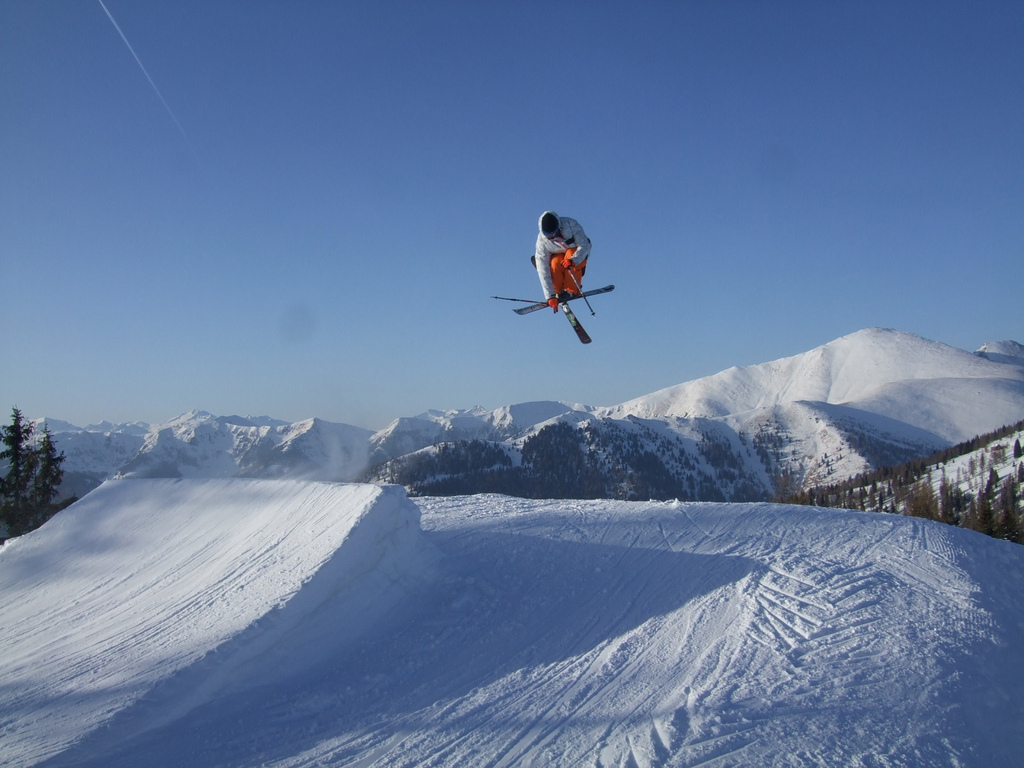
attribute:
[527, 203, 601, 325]
person — sking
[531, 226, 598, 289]
sweater — grey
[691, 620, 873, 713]
snow — white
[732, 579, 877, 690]
snow — white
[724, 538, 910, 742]
snow — white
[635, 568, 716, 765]
snow — white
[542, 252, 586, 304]
pants — orange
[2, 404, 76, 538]
trees — tall, green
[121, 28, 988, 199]
sky — blue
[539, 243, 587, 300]
pants — orange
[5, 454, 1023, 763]
snow — white